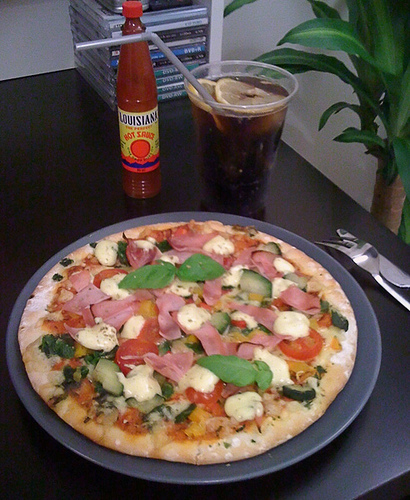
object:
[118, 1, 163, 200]
bottle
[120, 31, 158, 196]
sauce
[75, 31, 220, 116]
straw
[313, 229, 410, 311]
fork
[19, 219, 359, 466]
pizza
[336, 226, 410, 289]
knife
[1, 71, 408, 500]
table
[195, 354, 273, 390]
basil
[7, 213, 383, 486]
plate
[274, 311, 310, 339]
cheese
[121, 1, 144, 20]
cap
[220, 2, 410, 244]
plant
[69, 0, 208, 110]
stack of cds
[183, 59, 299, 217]
cup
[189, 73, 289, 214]
liquid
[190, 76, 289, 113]
slices of lemon